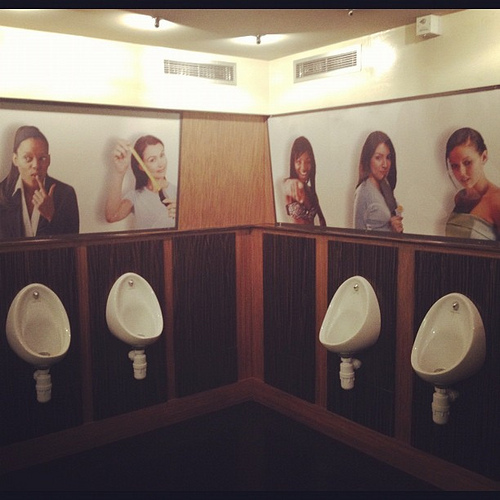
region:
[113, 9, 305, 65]
light reflections on ceiling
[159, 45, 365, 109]
two metal plates on wall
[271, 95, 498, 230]
picture of three women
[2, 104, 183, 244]
picture of two women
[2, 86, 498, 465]
pictures on two walls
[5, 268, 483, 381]
four white urinals on walls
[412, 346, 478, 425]
plastic pipe under urinal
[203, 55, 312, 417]
corner of two walls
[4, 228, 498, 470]
wood panels behind urinals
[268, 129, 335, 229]
woman in picture pointing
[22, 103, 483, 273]
The women watch you pee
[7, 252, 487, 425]
There are four urinals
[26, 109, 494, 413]
Pictures of woman in front of urinals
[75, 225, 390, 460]
The walls are wooden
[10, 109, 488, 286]
The women all look happy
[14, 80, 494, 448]
This is a men's restroom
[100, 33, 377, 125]
There are two air vents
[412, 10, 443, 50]
the smoke alarm is white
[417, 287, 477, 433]
The urinals are round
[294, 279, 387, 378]
The urinals are white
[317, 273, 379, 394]
A white urinal on the wall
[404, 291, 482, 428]
A white urinal on the wall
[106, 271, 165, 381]
A white urinal on the wall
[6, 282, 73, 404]
A white urinal on the wall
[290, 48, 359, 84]
A vent on the wall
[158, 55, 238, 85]
A vent on the wall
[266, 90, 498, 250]
A picture of women on the wall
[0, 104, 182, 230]
A picture of women on the wall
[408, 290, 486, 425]
A urinal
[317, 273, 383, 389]
A urinal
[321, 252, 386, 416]
urinal on a bathroom wall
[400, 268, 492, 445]
urinal on a bathroom wall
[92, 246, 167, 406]
urinal on a bathroom wall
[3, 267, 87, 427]
urinal on a bathroom wall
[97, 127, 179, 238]
picture of a woman holding a tape measure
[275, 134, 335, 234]
picture of a woman pointing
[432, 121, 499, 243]
picture of a woman judging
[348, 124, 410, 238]
picture of a woman holding a knife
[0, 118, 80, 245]
picture of a woman touching her lips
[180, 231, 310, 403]
wood paneling on the walls of a bathroom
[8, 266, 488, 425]
fur white urinals attached to wood paneled wall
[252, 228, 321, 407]
wood panel on wall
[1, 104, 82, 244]
photograph marketing portrait of person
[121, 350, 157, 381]
white pipes under urinal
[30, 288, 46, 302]
metal button on urinal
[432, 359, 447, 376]
metal drain in urinal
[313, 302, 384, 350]
bowl section of urinal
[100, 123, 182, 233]
woman holding out tape measure in photograph on wall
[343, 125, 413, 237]
woman in blue shirt holding object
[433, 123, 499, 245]
woman in gown and hair bun